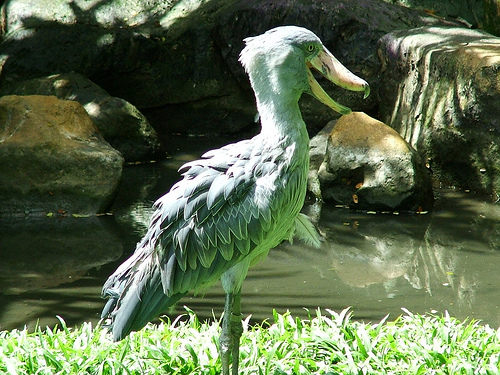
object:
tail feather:
[106, 255, 170, 342]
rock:
[377, 28, 500, 206]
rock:
[1, 2, 466, 138]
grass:
[0, 306, 500, 375]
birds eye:
[303, 42, 315, 54]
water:
[0, 164, 500, 327]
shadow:
[0, 0, 436, 113]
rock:
[0, 95, 125, 219]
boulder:
[306, 110, 424, 208]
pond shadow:
[0, 140, 500, 333]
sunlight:
[0, 0, 201, 28]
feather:
[295, 213, 322, 245]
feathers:
[101, 142, 305, 343]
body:
[95, 127, 311, 343]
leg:
[219, 274, 244, 375]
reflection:
[327, 221, 500, 298]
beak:
[306, 46, 370, 115]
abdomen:
[213, 187, 281, 268]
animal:
[101, 26, 370, 375]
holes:
[342, 169, 367, 188]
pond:
[0, 135, 500, 332]